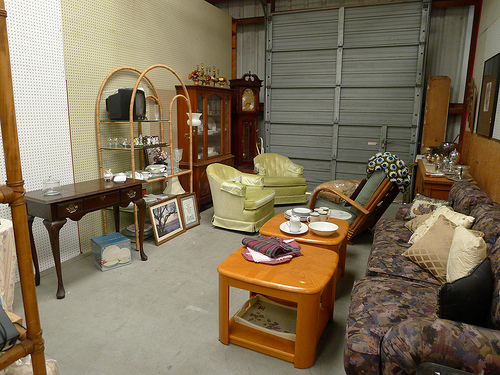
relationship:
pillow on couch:
[445, 226, 487, 283] [345, 166, 497, 373]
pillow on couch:
[435, 255, 496, 328] [345, 166, 497, 373]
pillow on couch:
[402, 212, 484, 282] [345, 166, 497, 373]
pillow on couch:
[406, 202, 473, 244] [345, 166, 497, 373]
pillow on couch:
[405, 210, 431, 231] [345, 166, 497, 373]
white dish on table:
[278, 220, 308, 235] [259, 208, 349, 288]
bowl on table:
[308, 222, 339, 237] [259, 208, 349, 288]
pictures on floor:
[147, 197, 185, 244] [15, 193, 401, 374]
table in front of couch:
[258, 212, 349, 277] [342, 181, 499, 375]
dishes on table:
[279, 206, 340, 236] [258, 204, 348, 244]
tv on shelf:
[103, 87, 162, 127] [91, 66, 205, 223]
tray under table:
[232, 293, 297, 343] [216, 243, 339, 369]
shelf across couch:
[92, 58, 202, 256] [342, 181, 499, 375]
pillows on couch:
[404, 194, 489, 329] [345, 166, 497, 373]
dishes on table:
[273, 206, 344, 238] [259, 208, 349, 288]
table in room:
[216, 231, 333, 350] [0, 0, 499, 371]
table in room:
[258, 212, 349, 277] [0, 0, 499, 371]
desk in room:
[23, 176, 147, 300] [0, 0, 499, 371]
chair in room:
[288, 121, 435, 283] [0, 0, 499, 371]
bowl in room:
[307, 220, 338, 235] [0, 0, 499, 371]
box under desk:
[90, 230, 131, 272] [23, 176, 147, 300]